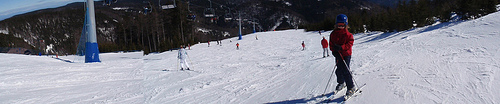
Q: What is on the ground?
A: Snow.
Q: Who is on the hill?
A: Skiers.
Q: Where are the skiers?
A: On the hill.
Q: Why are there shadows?
A: It is sunny.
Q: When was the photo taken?
A: Daytime.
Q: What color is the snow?
A: White.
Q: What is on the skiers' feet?
A: Skis.